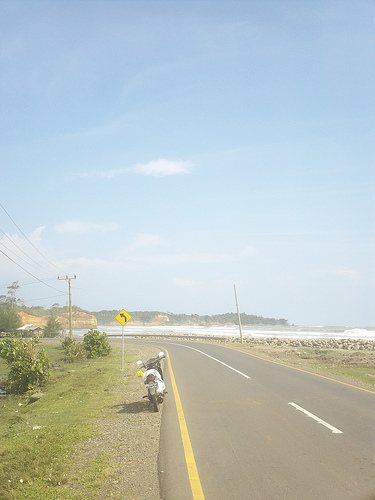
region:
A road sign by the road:
[120, 313, 125, 322]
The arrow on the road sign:
[121, 314, 124, 318]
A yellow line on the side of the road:
[177, 405, 181, 414]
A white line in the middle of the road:
[310, 414, 314, 416]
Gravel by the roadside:
[138, 426, 154, 449]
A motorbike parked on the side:
[148, 363, 155, 386]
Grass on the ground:
[69, 400, 80, 424]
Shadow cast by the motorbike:
[130, 405, 139, 410]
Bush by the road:
[16, 359, 29, 384]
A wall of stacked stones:
[335, 342, 367, 347]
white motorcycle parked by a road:
[134, 348, 173, 414]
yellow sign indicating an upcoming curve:
[113, 308, 132, 327]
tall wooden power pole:
[56, 272, 78, 346]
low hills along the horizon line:
[4, 304, 291, 327]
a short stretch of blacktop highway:
[162, 341, 373, 497]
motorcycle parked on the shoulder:
[136, 353, 168, 413]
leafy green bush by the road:
[83, 330, 109, 358]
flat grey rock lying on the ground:
[26, 390, 44, 402]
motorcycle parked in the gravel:
[130, 352, 171, 414]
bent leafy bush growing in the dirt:
[2, 334, 50, 400]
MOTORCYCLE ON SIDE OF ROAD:
[133, 349, 173, 411]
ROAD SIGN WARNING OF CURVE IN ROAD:
[109, 307, 138, 330]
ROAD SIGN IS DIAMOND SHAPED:
[110, 307, 136, 327]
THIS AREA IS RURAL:
[5, 295, 368, 480]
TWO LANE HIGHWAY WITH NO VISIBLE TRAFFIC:
[156, 337, 364, 486]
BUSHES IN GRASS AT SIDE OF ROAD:
[2, 324, 112, 409]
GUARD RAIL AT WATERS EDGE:
[96, 328, 240, 350]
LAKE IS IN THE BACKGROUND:
[62, 320, 373, 353]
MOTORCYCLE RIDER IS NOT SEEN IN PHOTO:
[125, 352, 181, 412]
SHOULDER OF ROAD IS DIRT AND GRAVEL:
[116, 339, 174, 494]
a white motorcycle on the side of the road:
[133, 349, 168, 411]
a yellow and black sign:
[113, 307, 132, 325]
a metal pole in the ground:
[120, 326, 126, 367]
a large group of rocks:
[133, 331, 374, 349]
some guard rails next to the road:
[99, 331, 229, 342]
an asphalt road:
[2, 335, 373, 498]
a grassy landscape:
[1, 338, 144, 496]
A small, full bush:
[84, 328, 110, 359]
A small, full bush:
[0, 332, 51, 392]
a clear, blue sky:
[0, 1, 374, 328]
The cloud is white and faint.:
[64, 155, 200, 180]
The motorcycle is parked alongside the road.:
[96, 304, 179, 497]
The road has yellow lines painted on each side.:
[109, 326, 374, 499]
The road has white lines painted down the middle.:
[103, 321, 371, 496]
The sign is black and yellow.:
[112, 307, 133, 376]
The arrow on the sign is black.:
[110, 296, 134, 379]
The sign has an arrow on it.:
[112, 304, 131, 381]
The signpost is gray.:
[112, 305, 138, 376]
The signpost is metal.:
[112, 299, 136, 373]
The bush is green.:
[79, 324, 112, 364]